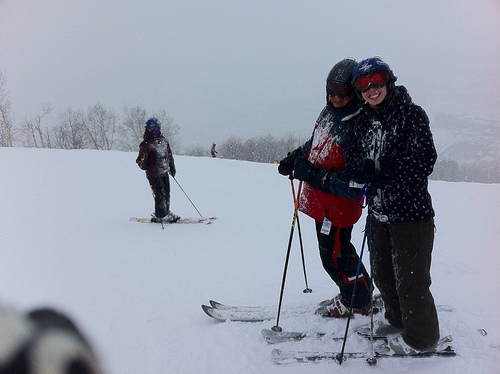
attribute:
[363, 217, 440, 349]
pants — grey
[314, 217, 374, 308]
pants — grey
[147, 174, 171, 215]
pants — grey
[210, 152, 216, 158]
pants — grey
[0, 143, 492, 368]
snow — white, thick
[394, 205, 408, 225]
dot — white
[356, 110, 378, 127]
dot — white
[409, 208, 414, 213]
dot — white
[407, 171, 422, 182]
dot — white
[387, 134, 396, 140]
dot — white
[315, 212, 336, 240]
lift pass — white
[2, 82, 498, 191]
trees — bare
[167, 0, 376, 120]
sky — grey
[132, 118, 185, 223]
person — skiing